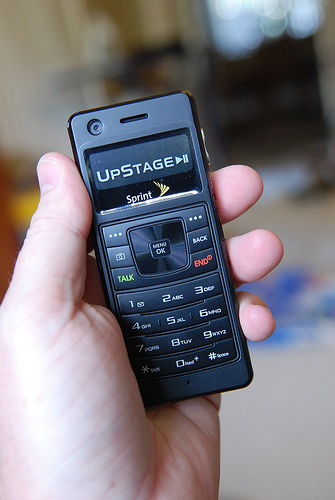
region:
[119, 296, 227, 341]
the keypad on the cellphone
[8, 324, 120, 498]
a persons hand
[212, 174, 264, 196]
a persons finger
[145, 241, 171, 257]
the menu button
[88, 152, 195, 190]
screen of the cellphone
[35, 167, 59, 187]
a thumb nail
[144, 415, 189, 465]
the persons palm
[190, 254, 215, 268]
the end button is red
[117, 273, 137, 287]
the talk button is green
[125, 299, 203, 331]
the numbers are white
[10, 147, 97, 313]
thumb of a person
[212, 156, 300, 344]
fingers of a person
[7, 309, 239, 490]
palm of a person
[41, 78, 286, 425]
person holding a cell phone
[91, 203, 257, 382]
key pads on a cell phone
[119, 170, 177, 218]
company brand on cell phone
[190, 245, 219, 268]
button on a black cell phone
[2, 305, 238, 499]
the palm of a person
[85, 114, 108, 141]
the camera of a phone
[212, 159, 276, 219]
middle finger of a person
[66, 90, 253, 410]
the black cell phone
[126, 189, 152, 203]
the word SPRINT on the phone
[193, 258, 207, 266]
the word END on the phone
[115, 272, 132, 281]
the word TALK on the phone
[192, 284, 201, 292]
the number 3 on the phone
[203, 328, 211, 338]
the number 9 on the phone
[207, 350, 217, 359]
the # sign on the phone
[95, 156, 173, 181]
the word "UPSTAGE" on the phone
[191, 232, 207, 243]
the word BACK on the phone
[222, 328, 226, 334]
the letter "z" on the phone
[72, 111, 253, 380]
phone in the hand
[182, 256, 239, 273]
end button is in red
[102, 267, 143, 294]
talk button is in green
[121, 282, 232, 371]
numbers on the keypad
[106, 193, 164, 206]
name of carrier of phone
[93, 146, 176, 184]
word on the screen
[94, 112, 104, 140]
camera lens on the phone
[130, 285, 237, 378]
white numbers on keypad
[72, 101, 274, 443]
cell phone in the person's hand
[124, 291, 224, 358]
number pad on the cell phone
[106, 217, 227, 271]
menu buttons on the cell phone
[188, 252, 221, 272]
red end button on the phone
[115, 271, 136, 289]
green talk button on the phone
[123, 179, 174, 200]
sprint logo on the phone screen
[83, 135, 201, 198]
screen on the cell phone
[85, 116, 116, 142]
camera lens on the cell phone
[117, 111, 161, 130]
speaker on the cell phone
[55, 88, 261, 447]
a sprint cell phone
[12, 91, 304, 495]
hand holding a cell phone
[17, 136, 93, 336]
thumb on the hand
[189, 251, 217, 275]
a red end button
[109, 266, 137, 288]
a green talk button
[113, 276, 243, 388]
numbers on the phone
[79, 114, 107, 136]
lense on the phone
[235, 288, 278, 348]
tip of the pinky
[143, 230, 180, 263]
middle button on the phone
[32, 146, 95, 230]
a human finger tip